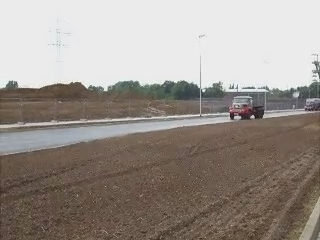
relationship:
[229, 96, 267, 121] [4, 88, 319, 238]
truck on ground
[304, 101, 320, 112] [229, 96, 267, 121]
truck behind a truck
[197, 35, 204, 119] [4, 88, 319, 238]
pole next to ground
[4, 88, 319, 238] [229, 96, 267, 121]
ground beneath truck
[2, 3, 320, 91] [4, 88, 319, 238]
sky above ground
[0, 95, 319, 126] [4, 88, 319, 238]
fence beside ground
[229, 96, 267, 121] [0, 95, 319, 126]
truck beside fence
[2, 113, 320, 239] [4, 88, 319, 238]
dirt covering ground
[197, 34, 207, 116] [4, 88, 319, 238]
light beside ground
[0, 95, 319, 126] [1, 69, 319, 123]
fence in background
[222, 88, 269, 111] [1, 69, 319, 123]
house in background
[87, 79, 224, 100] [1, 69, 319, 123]
trees are in background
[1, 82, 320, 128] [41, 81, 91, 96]
dirt in a pile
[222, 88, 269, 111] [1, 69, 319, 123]
building in background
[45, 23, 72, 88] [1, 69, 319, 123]
tower in background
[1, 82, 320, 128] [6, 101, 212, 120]
dirt in a patch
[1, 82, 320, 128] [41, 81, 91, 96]
dirt in a mound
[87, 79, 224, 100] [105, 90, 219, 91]
trees are in a line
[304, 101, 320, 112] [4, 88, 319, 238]
truck on ground